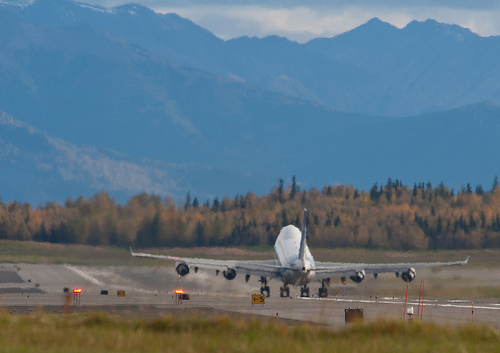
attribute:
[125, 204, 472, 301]
plane — leaving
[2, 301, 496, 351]
grass — green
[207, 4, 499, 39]
sky — blue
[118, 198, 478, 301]
jet — white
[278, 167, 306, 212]
tree — green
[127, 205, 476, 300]
airplane — white